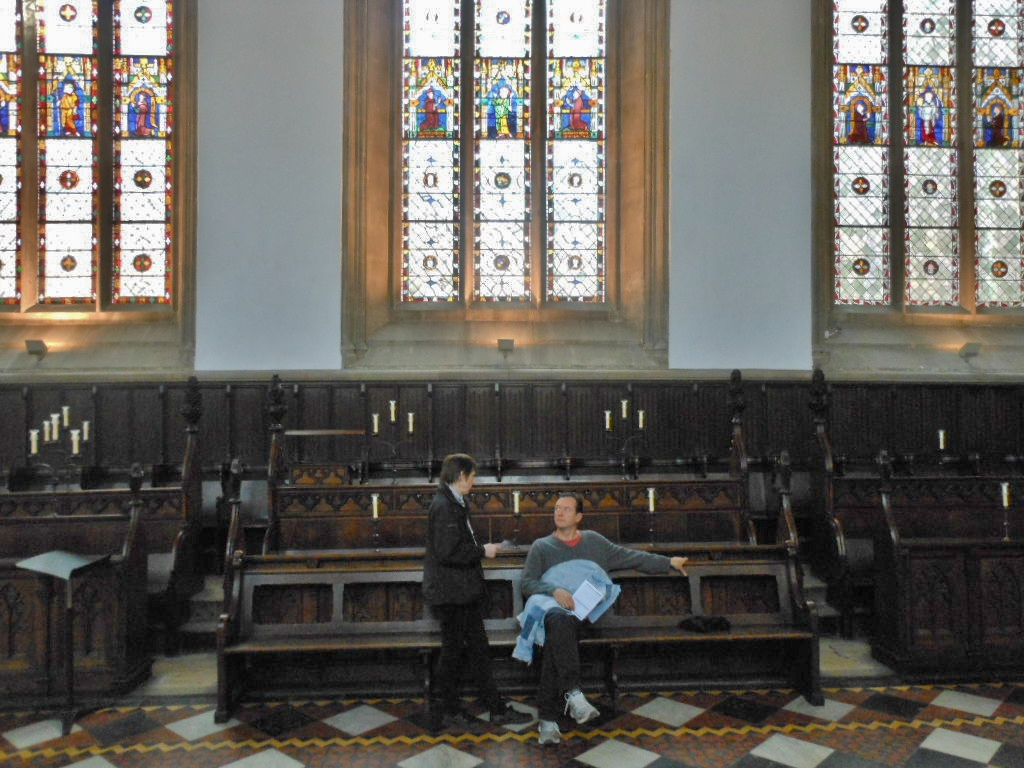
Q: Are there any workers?
A: No, there are no workers.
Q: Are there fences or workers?
A: No, there are no workers or fences.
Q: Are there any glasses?
A: No, there are no glasses.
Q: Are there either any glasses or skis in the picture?
A: No, there are no glasses or skis.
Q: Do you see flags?
A: No, there are no flags.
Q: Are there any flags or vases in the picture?
A: No, there are no flags or vases.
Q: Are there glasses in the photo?
A: No, there are no glasses.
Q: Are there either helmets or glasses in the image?
A: No, there are no glasses or helmets.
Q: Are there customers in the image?
A: No, there are no customers.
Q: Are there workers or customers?
A: No, there are no customers or workers.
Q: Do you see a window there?
A: Yes, there is a window.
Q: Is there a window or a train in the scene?
A: Yes, there is a window.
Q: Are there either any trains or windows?
A: Yes, there is a window.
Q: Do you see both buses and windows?
A: No, there is a window but no buses.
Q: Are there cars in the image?
A: No, there are no cars.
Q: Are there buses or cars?
A: No, there are no cars or buses.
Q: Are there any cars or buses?
A: No, there are no cars or buses.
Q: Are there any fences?
A: No, there are no fences.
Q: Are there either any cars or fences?
A: No, there are no fences or cars.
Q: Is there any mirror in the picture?
A: No, there are no mirrors.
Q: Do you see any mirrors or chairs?
A: No, there are no mirrors or chairs.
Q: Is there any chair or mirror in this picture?
A: No, there are no mirrors or chairs.